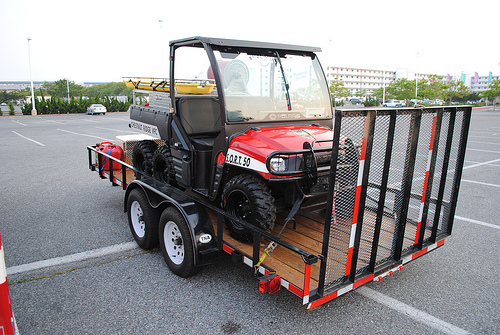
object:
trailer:
[87, 32, 472, 310]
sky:
[0, 0, 499, 80]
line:
[10, 129, 45, 149]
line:
[6, 238, 138, 276]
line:
[353, 284, 473, 334]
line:
[365, 156, 498, 194]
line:
[57, 127, 114, 142]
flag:
[486, 69, 494, 93]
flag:
[470, 69, 480, 94]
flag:
[457, 72, 469, 86]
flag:
[444, 71, 454, 84]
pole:
[487, 69, 492, 94]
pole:
[470, 72, 482, 93]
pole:
[456, 72, 470, 91]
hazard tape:
[94, 166, 128, 188]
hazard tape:
[222, 245, 300, 299]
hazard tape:
[302, 263, 310, 304]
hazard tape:
[344, 117, 369, 275]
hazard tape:
[414, 112, 438, 244]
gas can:
[88, 138, 127, 180]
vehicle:
[113, 23, 375, 258]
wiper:
[270, 48, 295, 110]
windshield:
[206, 35, 339, 124]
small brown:
[86, 102, 476, 311]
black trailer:
[87, 101, 473, 312]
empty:
[331, 103, 473, 289]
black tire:
[218, 172, 278, 244]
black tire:
[151, 142, 177, 188]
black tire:
[130, 137, 157, 179]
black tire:
[158, 203, 207, 278]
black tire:
[123, 186, 160, 251]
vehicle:
[86, 100, 110, 118]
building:
[322, 64, 394, 101]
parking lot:
[0, 101, 499, 326]